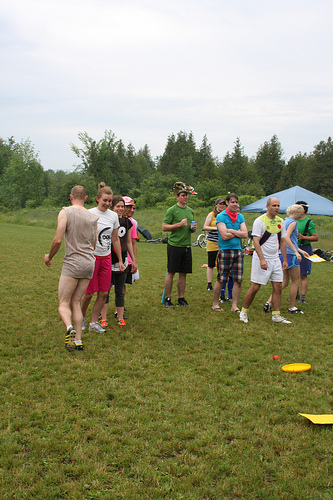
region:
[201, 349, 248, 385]
part of some grass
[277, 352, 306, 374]
part of a yellow top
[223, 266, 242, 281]
part of a short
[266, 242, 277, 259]
part of a white top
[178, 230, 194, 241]
part of a green top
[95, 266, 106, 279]
part of a pink top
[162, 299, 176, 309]
part of a shoe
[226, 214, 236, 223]
part of a scarf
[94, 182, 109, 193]
hair of a lady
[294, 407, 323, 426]
part of a paper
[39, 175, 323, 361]
group of people in the park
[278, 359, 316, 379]
yellow Frisbee on the grass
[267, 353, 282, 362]
red ball on the grass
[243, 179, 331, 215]
blue tent in the back grassy area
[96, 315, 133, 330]
orange sneakers of a woman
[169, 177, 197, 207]
man with silly hat on head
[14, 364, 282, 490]
green grassy area where people are standing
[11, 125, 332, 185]
green trees in the background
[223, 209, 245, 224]
red scarf of a man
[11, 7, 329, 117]
cloudy sky in the background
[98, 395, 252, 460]
the grass is green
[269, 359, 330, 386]
the frisbee is yellow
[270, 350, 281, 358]
the ball is red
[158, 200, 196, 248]
the man has green shirt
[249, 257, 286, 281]
the shorts are white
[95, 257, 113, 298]
the short is orange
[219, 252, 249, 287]
the short is checked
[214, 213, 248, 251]
the shirt is blue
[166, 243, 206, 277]
the short is black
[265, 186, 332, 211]
the tent is blue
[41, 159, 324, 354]
group of people in field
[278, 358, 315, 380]
yellow frisbee on grass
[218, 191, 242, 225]
man wearing red handkerchief around neck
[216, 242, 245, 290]
man wearing plaid shorts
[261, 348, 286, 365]
red ball laying on grass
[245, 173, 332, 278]
tent standing beside field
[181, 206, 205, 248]
man holding can of beverage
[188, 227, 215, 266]
bicycle laying on the ground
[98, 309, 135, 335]
woman wearing orange shoes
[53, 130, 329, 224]
tall trees in background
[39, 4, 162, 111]
this is the sky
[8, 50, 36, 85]
the sky is blue in color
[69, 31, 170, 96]
these are clouds in the sky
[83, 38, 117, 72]
the clouds are white in color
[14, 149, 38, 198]
this is a tree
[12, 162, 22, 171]
the tree has green leaves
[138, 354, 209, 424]
this is a grass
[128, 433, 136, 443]
the grass is green in color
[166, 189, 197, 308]
this is a man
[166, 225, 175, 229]
the man has a light skin